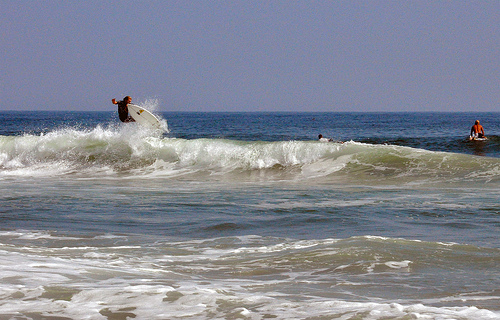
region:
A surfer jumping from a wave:
[111, 94, 168, 135]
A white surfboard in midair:
[126, 102, 169, 134]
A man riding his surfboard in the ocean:
[468, 118, 488, 140]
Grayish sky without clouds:
[3, 3, 499, 113]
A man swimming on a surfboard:
[316, 132, 344, 144]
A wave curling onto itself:
[178, 135, 355, 187]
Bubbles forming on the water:
[2, 204, 497, 309]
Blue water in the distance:
[203, 112, 301, 139]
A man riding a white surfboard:
[113, 95, 170, 135]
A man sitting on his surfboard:
[469, 120, 487, 142]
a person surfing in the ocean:
[110, 92, 165, 133]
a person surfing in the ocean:
[316, 131, 345, 143]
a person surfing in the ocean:
[469, 117, 486, 142]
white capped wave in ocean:
[2, 134, 55, 161]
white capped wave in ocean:
[93, 130, 169, 170]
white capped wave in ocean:
[186, 140, 271, 177]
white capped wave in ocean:
[279, 137, 343, 169]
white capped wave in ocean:
[358, 139, 420, 164]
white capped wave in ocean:
[311, 231, 430, 255]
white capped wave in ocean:
[36, 230, 146, 258]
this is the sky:
[245, 7, 422, 76]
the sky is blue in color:
[326, 10, 394, 71]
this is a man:
[462, 111, 480, 143]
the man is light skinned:
[473, 120, 485, 127]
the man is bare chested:
[468, 122, 483, 130]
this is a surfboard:
[123, 93, 174, 145]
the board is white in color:
[137, 107, 152, 117]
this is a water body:
[247, 107, 329, 140]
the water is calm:
[245, 110, 271, 138]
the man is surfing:
[96, 82, 184, 156]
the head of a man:
[121, 67, 152, 116]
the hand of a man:
[91, 79, 118, 128]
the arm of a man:
[96, 84, 134, 119]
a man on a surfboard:
[97, 58, 168, 130]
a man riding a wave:
[100, 45, 200, 176]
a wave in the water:
[56, 69, 270, 201]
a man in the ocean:
[68, 60, 237, 178]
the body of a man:
[102, 51, 163, 146]